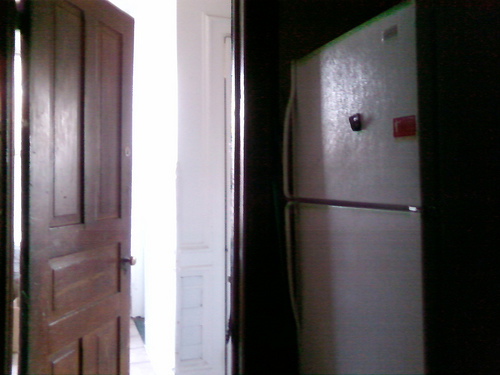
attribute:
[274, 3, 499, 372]
refrigerator — white, metallic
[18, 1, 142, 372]
door — open, brown, wooden, big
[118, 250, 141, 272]
doorknob — yellow, brass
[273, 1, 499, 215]
freezer — white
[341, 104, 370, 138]
magnet — blue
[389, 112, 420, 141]
magnet — red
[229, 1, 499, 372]
room — black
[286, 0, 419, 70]
line — green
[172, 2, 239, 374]
door — white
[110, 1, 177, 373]
wall — white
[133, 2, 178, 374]
light — bright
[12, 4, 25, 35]
hinge — metal